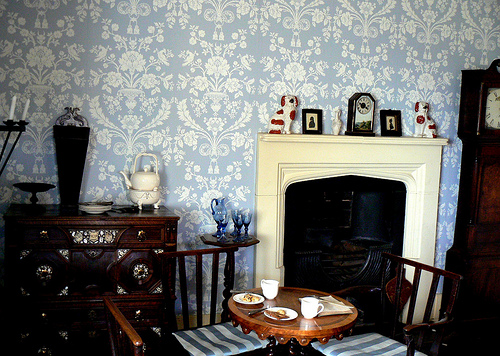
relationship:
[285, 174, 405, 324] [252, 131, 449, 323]
fireplace with a mantel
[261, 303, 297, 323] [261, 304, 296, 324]
snack on saucer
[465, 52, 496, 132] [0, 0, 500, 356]
clock in kitchen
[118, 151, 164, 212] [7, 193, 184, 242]
kettle on shelf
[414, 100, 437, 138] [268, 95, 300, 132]
figurine of dog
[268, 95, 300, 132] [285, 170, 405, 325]
dog on fireplace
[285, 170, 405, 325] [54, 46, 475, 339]
fireplace in kitchen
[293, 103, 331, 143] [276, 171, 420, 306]
photo on fireplace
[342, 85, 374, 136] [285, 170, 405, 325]
clock on fireplace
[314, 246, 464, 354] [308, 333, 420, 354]
chair with stripes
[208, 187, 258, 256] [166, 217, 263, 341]
glassware on table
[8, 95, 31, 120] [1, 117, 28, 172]
candles in holders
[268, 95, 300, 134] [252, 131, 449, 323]
dog on mantel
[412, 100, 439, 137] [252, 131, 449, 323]
figurine on mantel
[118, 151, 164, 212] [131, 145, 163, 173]
kettle with handle